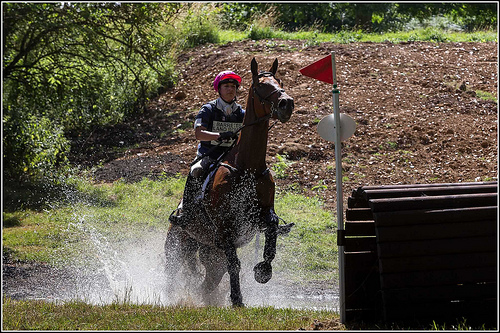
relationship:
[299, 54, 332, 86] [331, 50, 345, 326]
flag on pole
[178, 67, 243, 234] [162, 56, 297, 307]
jockey on horse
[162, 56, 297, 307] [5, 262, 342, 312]
horse running through creek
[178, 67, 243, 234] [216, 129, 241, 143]
jockey wearing glove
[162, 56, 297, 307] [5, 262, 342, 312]
horse galloping through creek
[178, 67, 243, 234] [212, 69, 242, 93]
jockey wearing helmet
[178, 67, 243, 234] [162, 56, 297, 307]
jockey riding horse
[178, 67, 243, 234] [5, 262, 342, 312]
jockey riding through creek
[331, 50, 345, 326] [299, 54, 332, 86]
pole has flag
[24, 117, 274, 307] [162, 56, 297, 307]
water spraying horse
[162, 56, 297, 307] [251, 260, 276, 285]
horse has hoof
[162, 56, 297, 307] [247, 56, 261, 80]
horse has ear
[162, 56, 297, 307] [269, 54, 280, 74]
horse has ear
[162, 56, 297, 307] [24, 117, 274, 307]
horse running through water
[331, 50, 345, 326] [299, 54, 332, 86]
pole holding flag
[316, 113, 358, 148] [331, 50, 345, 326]
sign on pole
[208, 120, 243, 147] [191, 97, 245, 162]
sign on uniform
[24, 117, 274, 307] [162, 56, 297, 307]
water splashing around horse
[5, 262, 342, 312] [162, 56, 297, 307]
creek near horse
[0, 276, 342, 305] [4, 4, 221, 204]
water in woods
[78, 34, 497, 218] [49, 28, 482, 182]
dirt on hill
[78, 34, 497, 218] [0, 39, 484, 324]
dirt on ground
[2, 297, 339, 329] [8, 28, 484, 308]
grass on ground